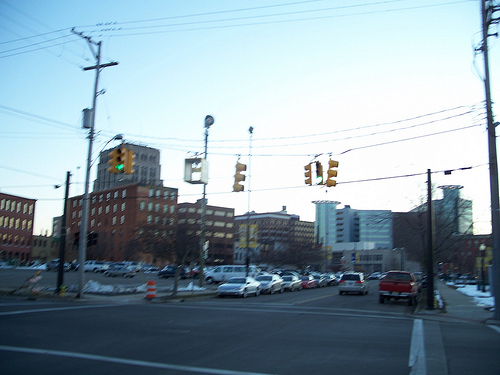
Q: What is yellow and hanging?
A: Traffic lights.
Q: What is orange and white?
A: Traffic barrel.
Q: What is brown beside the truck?
A: A telephone pole.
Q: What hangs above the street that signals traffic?
A: Traffic lights.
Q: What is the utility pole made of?
A: Metal.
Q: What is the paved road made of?
A: Concrete.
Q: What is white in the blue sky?
A: Clouds.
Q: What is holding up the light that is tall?
A: Pole.